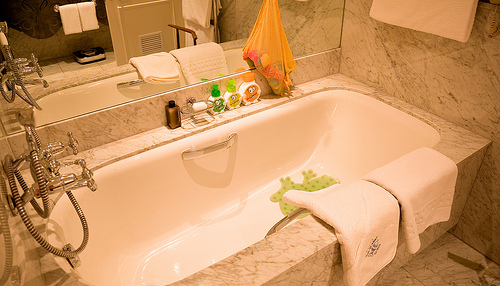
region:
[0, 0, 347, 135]
A mirror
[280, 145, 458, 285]
A pair of towels on the edge of the tub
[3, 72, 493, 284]
A bathtub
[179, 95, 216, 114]
A soap dish attached to the wall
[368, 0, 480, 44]
A towel hanging on the wall above a bathtub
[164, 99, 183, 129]
A brown bottle with a black cap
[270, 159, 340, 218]
A bath mat in the shape of a frog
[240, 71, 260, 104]
An orange and white bottle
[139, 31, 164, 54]
An air vent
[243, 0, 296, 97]
An orange bag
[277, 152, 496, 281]
two white towels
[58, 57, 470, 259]
two white towels on the side of a bath tub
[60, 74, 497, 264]
two white towels on the side of a white tub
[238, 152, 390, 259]
green frog bath mat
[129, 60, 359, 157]
bottles of soap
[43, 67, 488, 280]
bottles of soap on the side of a tub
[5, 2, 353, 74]
a mirror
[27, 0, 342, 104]
a mirror next to a white tub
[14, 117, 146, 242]
silver bath handles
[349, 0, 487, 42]
a white towel hanging on the wall in a bathroom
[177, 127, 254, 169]
handle on the inside of the bathtub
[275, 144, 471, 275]
two white towels on edge of bathtub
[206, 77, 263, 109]
three childrens soaps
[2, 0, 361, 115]
a mirror makes the wall next to bathtub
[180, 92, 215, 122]
a bar of soap on a soap tray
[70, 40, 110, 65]
reflection of a scale on the floor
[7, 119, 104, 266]
silver hose and handles to turn water on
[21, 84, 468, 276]
a clean empty bathtub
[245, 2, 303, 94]
a net with bath toys in it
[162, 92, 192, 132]
a small copper colored bottle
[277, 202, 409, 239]
White towel on a tub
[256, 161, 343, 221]
Green frog in a tub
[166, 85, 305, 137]
Soap by a tub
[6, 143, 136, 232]
Silver faucet on a tub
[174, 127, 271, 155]
Silver handle on a tub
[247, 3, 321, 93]
Orange bag in a tub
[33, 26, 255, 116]
Mirror by a tub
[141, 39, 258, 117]
Two white towels in a mirror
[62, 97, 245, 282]
Gray stone around a tub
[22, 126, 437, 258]
White bathtub in a bathroom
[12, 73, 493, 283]
an elegant looking bathtub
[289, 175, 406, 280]
a bath towel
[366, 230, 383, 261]
an emblem on a bath towel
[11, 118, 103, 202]
a faucet on a bathtub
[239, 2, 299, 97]
a mesh bag with bath toys in it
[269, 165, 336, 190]
an anti-slip mat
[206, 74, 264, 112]
children's bath products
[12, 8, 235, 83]
a glass mirror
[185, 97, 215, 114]
a bar of soap on a soap rack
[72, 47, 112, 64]
the reflection of a scale in a mirror